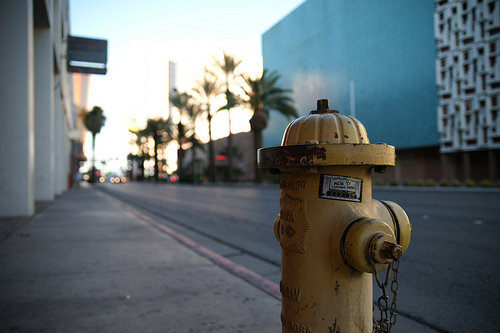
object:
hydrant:
[255, 97, 412, 331]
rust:
[251, 138, 325, 172]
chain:
[367, 256, 401, 332]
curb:
[94, 188, 279, 321]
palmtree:
[237, 66, 300, 186]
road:
[87, 174, 500, 333]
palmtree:
[210, 50, 247, 185]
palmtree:
[193, 66, 223, 180]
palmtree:
[185, 101, 206, 183]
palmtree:
[169, 84, 193, 183]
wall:
[253, 0, 441, 157]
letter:
[280, 279, 285, 294]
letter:
[284, 285, 289, 295]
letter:
[292, 284, 302, 303]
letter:
[281, 208, 287, 217]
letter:
[288, 208, 294, 222]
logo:
[277, 191, 310, 255]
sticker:
[320, 172, 364, 203]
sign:
[66, 31, 111, 75]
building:
[0, 0, 79, 220]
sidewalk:
[1, 180, 282, 333]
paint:
[257, 106, 397, 194]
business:
[67, 35, 106, 187]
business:
[175, 126, 261, 180]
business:
[435, 0, 499, 185]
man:
[74, 168, 82, 192]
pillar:
[0, 0, 36, 220]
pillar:
[37, 17, 52, 209]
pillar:
[57, 99, 67, 194]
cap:
[255, 98, 397, 168]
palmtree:
[84, 104, 107, 187]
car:
[113, 173, 126, 180]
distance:
[81, 94, 157, 195]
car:
[101, 177, 113, 182]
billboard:
[163, 58, 207, 128]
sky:
[69, 1, 304, 176]